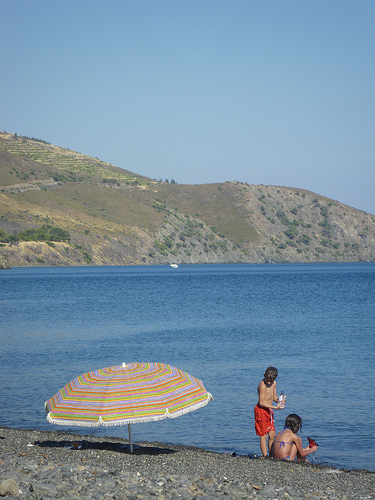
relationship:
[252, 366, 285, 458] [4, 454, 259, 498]
boy standing on beach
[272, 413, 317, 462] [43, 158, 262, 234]
girl sitting on ground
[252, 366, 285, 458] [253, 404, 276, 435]
boy wearing shorts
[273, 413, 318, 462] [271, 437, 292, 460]
girl wearing bathing suit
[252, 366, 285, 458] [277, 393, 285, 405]
boy holding bottle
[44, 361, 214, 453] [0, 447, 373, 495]
umbrella stuck in ground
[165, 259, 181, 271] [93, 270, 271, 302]
boat floating in water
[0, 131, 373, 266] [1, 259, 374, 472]
hillside next to water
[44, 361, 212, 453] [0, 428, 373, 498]
umbrella on beach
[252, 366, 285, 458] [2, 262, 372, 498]
boy playing on beach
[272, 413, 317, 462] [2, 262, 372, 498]
girl playing on beach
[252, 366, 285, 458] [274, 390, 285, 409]
boy holding water bottle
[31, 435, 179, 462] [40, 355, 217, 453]
shade from umbrella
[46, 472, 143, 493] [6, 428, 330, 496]
rocks in sand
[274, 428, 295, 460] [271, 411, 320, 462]
bathing suit of girl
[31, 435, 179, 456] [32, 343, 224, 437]
shade of umbrella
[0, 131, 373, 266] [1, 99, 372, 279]
hillside in background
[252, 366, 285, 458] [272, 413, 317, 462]
boy and a girl